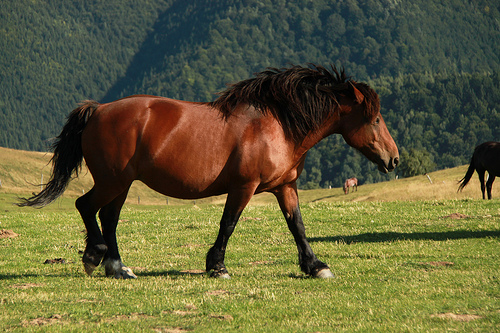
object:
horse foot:
[103, 255, 138, 279]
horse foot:
[205, 253, 231, 280]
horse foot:
[296, 251, 335, 280]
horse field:
[0, 141, 495, 330]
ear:
[347, 79, 364, 105]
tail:
[456, 144, 482, 194]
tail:
[10, 100, 101, 210]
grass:
[234, 228, 291, 300]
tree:
[344, 54, 498, 195]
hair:
[15, 100, 95, 210]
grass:
[368, 211, 475, 328]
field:
[11, 111, 497, 317]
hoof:
[308, 262, 335, 279]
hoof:
[205, 263, 230, 280]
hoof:
[105, 267, 139, 279]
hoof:
[82, 251, 105, 276]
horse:
[14, 62, 400, 280]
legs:
[77, 209, 336, 279]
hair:
[212, 62, 346, 143]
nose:
[392, 156, 399, 168]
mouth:
[377, 162, 396, 174]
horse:
[343, 177, 358, 194]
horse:
[455, 139, 499, 199]